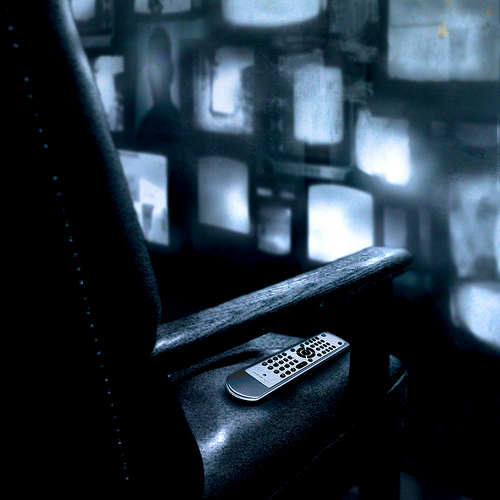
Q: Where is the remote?
A: Chair.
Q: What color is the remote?
A: Black.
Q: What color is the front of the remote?
A: Silver.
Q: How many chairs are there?
A: One.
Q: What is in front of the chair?
A: Stained glass.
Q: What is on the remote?
A: Buttons.